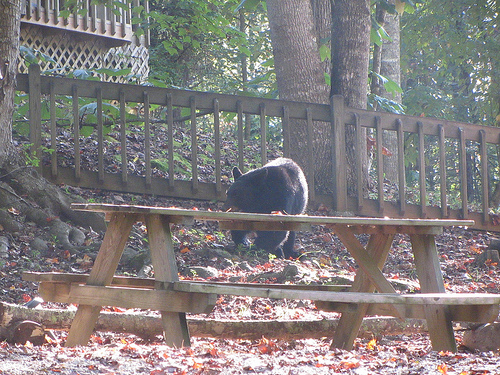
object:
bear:
[222, 156, 308, 259]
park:
[0, 146, 500, 374]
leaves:
[4, 191, 498, 375]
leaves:
[0, 0, 500, 176]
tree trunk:
[264, 1, 403, 193]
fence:
[0, 72, 500, 234]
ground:
[0, 265, 495, 373]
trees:
[0, 0, 500, 246]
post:
[142, 216, 191, 349]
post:
[59, 209, 136, 352]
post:
[399, 233, 455, 359]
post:
[330, 231, 394, 357]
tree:
[0, 0, 22, 234]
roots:
[0, 164, 105, 235]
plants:
[5, 89, 276, 186]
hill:
[7, 91, 274, 197]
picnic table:
[19, 201, 499, 352]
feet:
[225, 234, 303, 260]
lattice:
[1, 29, 148, 84]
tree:
[269, 0, 371, 202]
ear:
[229, 166, 244, 182]